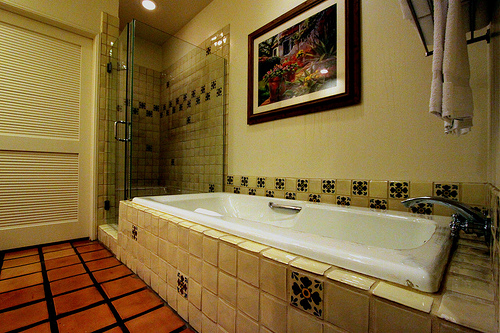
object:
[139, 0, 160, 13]
light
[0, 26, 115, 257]
white door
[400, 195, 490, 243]
faucet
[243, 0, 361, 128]
painting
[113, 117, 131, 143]
door handle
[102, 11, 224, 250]
shower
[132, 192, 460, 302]
bath tub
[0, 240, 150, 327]
floor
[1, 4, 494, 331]
bathroom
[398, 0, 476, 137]
towel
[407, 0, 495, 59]
rack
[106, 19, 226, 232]
glass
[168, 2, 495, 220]
wall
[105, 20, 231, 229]
door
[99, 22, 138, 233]
glass door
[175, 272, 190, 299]
tile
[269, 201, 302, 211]
bar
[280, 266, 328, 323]
tile